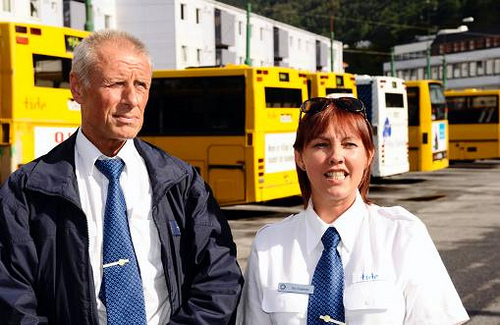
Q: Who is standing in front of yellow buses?
A: A man and a woman.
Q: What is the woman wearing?
A: A white shirt.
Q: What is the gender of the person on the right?
A: Female.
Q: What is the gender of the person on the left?
A: Male.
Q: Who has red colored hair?
A: The woman.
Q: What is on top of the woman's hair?
A: Glasses.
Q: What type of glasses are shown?
A: Sunglasses.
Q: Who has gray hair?
A: The man.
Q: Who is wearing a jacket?
A: The man.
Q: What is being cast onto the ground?
A: Shadows.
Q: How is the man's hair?
A: Short.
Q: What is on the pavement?
A: The pavement is wet.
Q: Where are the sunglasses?
A: In the woman's hair.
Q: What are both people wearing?
A: Ties.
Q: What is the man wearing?
A: A jacket.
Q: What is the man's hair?
A: Gray.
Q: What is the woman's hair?
A: Reddish color.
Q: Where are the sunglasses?
A: On the woman's head.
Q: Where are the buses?
A: Behind the two people.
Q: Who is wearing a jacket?
A: The man.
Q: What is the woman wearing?
A: A white shirt and blue tie.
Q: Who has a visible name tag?
A: The woman.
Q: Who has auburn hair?
A: The woman.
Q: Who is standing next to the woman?
A: The man.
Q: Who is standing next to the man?
A: The woman.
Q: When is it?
A: Day time.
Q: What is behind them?
A: Buses.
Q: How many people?
A: 2.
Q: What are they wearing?
A: Ties.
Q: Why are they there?
A: To talk.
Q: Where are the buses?
A: Behind the people.